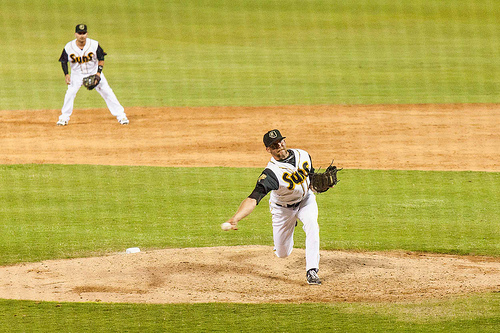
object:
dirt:
[0, 103, 500, 170]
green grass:
[1, 0, 500, 111]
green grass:
[0, 162, 499, 269]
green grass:
[0, 293, 500, 333]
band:
[97, 65, 104, 74]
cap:
[75, 23, 88, 33]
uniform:
[247, 148, 322, 271]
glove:
[310, 160, 344, 193]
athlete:
[223, 129, 319, 284]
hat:
[263, 129, 286, 146]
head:
[263, 129, 287, 157]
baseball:
[219, 222, 232, 230]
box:
[124, 246, 140, 255]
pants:
[58, 74, 126, 121]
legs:
[93, 71, 124, 119]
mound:
[0, 245, 500, 305]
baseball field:
[0, 0, 500, 333]